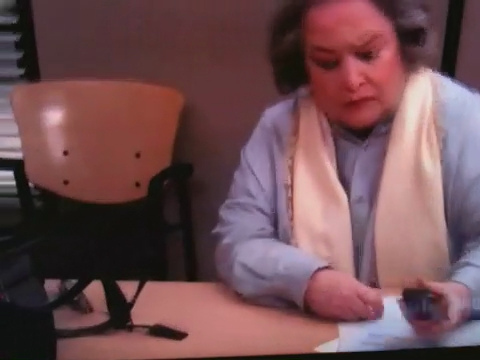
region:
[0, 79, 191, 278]
a black and wooden chair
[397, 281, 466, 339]
a cell phone in a woman's hand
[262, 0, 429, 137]
head of an old woman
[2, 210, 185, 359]
a black bag on a table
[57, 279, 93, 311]
glasses on a table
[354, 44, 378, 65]
closed eye of a woman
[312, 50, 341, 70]
closed eye of a woman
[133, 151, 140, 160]
black bolt on a chair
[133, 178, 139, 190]
black bolt on a chair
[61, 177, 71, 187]
black bolt on a chair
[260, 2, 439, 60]
woman has grey hair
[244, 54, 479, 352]
woman has blue shirt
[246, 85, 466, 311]
woman has white scarf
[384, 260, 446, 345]
woman is holding phone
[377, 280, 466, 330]
phone is black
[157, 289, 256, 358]
woman is at brown table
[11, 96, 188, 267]
chair next to woman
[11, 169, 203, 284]
chair has black arms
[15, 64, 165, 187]
chair has brown back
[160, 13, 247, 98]
tan wall behind woman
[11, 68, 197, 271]
a chair beside the lady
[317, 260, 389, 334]
the hand of a lady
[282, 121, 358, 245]
a scarf on the lady's shouder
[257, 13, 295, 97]
the lady's hair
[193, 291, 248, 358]
the table in the room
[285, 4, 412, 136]
the face of a lady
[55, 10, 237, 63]
curtain at the back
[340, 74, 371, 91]
the nose of a lady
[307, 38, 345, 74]
the lady of a lady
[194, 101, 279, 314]
the arm of a lady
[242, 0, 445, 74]
woman has dark hair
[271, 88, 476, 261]
woman has tan scarf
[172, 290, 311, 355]
woman has arms on brown table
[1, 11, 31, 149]
white blinds on window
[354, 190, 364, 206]
small button on the shirt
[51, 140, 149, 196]
four black dots on the chair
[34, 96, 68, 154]
light glare on the chair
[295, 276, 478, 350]
papers on the table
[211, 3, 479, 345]
woman sitting at a table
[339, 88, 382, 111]
lips are thin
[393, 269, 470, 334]
black object in the hand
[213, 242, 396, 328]
arm resting on the table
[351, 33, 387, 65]
thin eyebrow above the eye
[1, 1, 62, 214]
white blinds on the window